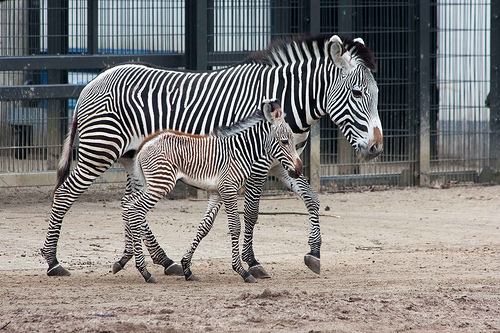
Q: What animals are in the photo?
A: Zebras.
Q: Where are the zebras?
A: In an enclosure.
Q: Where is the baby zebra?
A: Next to the mother.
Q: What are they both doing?
A: Walking.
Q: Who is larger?
A: The mother.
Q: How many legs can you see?
A: Eight.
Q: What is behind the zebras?
A: A fence.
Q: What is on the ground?
A: Dirt.